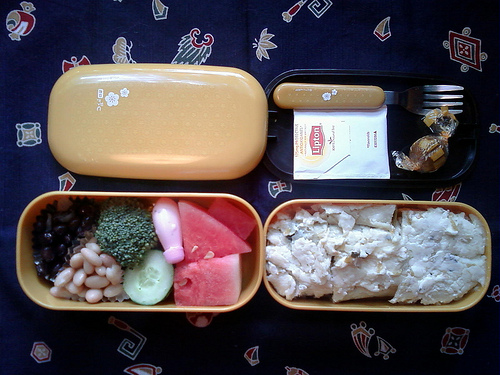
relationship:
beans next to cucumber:
[49, 245, 124, 301] [125, 249, 172, 305]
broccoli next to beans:
[97, 202, 158, 267] [49, 245, 124, 301]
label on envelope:
[310, 123, 328, 156] [295, 106, 391, 180]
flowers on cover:
[105, 85, 134, 110] [46, 64, 269, 181]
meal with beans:
[32, 200, 251, 306] [49, 245, 124, 301]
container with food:
[16, 190, 263, 313] [32, 200, 251, 306]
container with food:
[262, 200, 492, 312] [266, 204, 485, 304]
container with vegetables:
[16, 190, 263, 313] [35, 197, 176, 303]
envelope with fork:
[295, 106, 391, 180] [272, 84, 465, 114]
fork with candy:
[272, 84, 465, 114] [390, 107, 461, 173]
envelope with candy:
[295, 106, 391, 180] [390, 107, 461, 173]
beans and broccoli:
[49, 245, 124, 301] [97, 202, 158, 267]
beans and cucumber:
[49, 245, 124, 301] [125, 249, 172, 305]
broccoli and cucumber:
[97, 202, 158, 267] [125, 249, 172, 305]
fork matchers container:
[272, 84, 465, 114] [16, 190, 263, 313]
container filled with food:
[16, 190, 263, 313] [266, 204, 485, 304]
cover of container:
[46, 64, 269, 181] [16, 190, 263, 313]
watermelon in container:
[174, 202, 251, 306] [16, 190, 263, 313]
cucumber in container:
[125, 249, 172, 305] [16, 190, 263, 313]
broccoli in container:
[97, 202, 158, 267] [16, 190, 263, 313]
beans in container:
[49, 245, 124, 301] [16, 190, 263, 313]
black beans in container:
[35, 198, 99, 287] [16, 190, 263, 313]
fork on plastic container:
[272, 84, 465, 114] [263, 70, 478, 186]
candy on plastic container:
[390, 107, 461, 173] [263, 70, 478, 186]